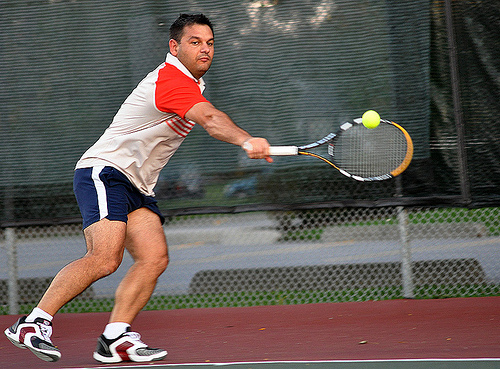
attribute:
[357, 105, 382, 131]
ball — yellow, round, green, flying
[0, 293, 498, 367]
surface — red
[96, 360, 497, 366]
surface — green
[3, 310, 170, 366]
shoes — multi colored, multi-colored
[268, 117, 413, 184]
racket — white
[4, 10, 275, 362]
man — hispanic, playing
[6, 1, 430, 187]
mesh — green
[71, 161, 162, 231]
shorts — blue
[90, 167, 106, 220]
stripe — white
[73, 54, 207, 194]
shirt — red, white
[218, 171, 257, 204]
vehicle — teal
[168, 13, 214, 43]
short hair — dark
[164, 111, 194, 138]
stripes — red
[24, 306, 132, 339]
socks — white